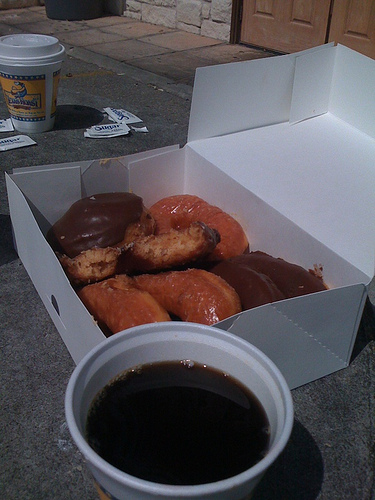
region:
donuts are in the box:
[0, 116, 362, 383]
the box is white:
[19, 48, 361, 383]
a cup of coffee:
[48, 315, 302, 496]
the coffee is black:
[58, 328, 299, 484]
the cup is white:
[21, 320, 318, 480]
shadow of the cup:
[275, 416, 343, 488]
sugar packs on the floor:
[56, 85, 145, 140]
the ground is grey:
[74, 77, 171, 138]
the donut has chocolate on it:
[39, 185, 161, 243]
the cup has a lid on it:
[3, 22, 87, 128]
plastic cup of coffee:
[59, 318, 307, 497]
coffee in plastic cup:
[81, 355, 280, 488]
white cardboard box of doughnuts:
[3, 32, 372, 398]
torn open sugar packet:
[100, 102, 145, 127]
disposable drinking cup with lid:
[0, 31, 73, 136]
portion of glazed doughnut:
[75, 277, 178, 337]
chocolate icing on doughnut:
[45, 190, 157, 261]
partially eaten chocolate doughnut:
[126, 222, 219, 273]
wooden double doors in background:
[238, 2, 371, 62]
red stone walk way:
[1, 0, 294, 92]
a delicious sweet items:
[90, 187, 279, 354]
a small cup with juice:
[63, 326, 297, 497]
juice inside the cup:
[109, 380, 257, 490]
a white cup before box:
[50, 333, 329, 498]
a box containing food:
[20, 148, 361, 496]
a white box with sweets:
[40, 158, 369, 316]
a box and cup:
[24, 158, 329, 486]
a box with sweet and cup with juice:
[63, 172, 246, 485]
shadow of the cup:
[267, 457, 355, 498]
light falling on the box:
[302, 90, 355, 129]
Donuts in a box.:
[50, 190, 334, 333]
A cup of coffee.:
[65, 318, 292, 499]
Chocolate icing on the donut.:
[46, 191, 140, 252]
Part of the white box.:
[277, 134, 343, 212]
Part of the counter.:
[11, 329, 45, 395]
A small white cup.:
[1, 35, 63, 135]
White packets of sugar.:
[85, 121, 131, 137]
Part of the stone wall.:
[150, 6, 208, 21]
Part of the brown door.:
[259, 11, 293, 35]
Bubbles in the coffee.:
[180, 356, 196, 368]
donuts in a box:
[21, 147, 348, 339]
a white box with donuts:
[20, 83, 370, 402]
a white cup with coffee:
[41, 327, 307, 498]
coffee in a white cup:
[47, 337, 318, 493]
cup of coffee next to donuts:
[24, 303, 299, 499]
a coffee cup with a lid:
[1, 25, 80, 143]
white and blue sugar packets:
[80, 96, 156, 150]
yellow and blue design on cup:
[2, 74, 51, 129]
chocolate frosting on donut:
[58, 189, 157, 248]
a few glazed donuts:
[90, 259, 253, 340]